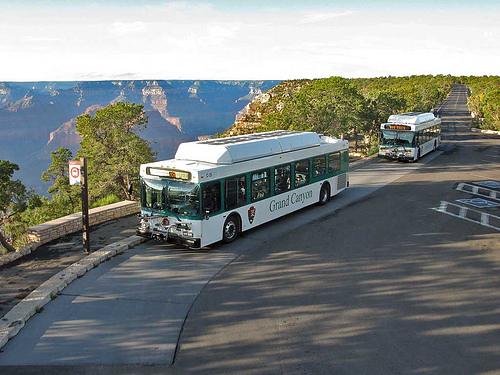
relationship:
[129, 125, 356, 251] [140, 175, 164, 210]
bus has windshield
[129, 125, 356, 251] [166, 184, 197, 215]
bus has windshield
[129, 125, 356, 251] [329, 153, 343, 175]
bus has window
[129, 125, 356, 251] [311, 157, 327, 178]
bus has window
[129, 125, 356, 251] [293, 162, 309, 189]
bus has window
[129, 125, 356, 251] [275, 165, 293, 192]
bus has window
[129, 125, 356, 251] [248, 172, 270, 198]
bus has window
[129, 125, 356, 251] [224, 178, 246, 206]
bus has window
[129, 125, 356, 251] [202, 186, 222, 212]
bus has window